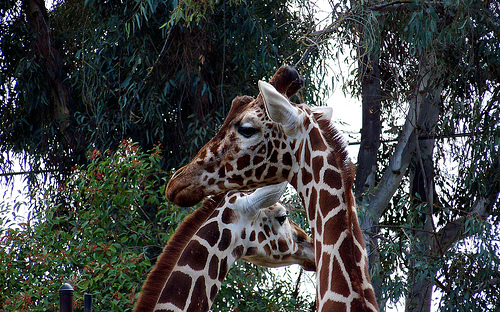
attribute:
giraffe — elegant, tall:
[141, 65, 411, 306]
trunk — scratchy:
[354, 75, 498, 301]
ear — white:
[258, 79, 297, 126]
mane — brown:
[133, 192, 220, 309]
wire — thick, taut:
[6, 123, 491, 153]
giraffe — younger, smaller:
[112, 58, 409, 307]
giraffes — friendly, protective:
[166, 64, 380, 310]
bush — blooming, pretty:
[0, 148, 182, 304]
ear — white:
[314, 100, 345, 127]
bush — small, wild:
[1, 139, 160, 310]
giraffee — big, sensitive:
[166, 65, 379, 310]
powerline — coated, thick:
[341, 127, 492, 167]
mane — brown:
[320, 115, 366, 242]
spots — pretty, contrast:
[284, 151, 368, 309]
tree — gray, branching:
[319, 17, 479, 295]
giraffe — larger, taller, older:
[169, 53, 399, 202]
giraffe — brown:
[124, 36, 458, 310]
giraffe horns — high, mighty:
[256, 65, 303, 107]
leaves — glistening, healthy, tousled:
[95, 15, 209, 122]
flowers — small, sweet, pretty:
[1, 131, 166, 310]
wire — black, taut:
[372, 90, 473, 157]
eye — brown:
[271, 201, 298, 232]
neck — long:
[138, 215, 236, 309]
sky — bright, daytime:
[244, 15, 416, 108]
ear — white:
[238, 185, 298, 216]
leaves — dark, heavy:
[346, 2, 498, 76]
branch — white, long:
[380, 187, 492, 299]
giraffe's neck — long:
[290, 152, 391, 309]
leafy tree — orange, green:
[45, 143, 147, 290]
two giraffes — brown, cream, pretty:
[127, 64, 383, 310]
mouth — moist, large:
[154, 172, 185, 205]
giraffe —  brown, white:
[131, 180, 317, 309]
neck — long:
[292, 150, 376, 310]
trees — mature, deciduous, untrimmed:
[354, 1, 462, 308]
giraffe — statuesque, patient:
[301, 179, 343, 244]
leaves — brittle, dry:
[71, 162, 154, 256]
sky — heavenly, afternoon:
[301, 13, 360, 127]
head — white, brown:
[151, 69, 354, 206]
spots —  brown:
[170, 216, 240, 308]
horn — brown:
[255, 63, 299, 108]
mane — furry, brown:
[305, 106, 375, 305]